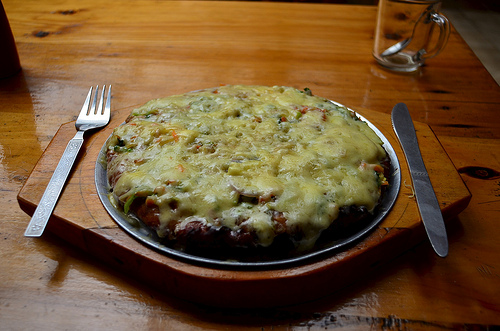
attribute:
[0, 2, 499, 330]
table — wooden, rustic, wood, varnished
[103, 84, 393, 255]
pizza — delicious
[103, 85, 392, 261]
cheese — goopy, green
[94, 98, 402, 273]
pan — silver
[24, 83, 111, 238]
fork — silver, long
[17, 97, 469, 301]
board — wood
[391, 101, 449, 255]
knife — silver, large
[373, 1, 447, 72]
glass — clear